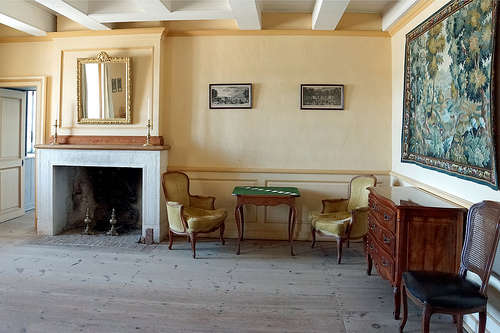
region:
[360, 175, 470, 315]
dark wood dresser beneath hanging rug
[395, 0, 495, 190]
decorative woven rug hanging on wall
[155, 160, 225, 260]
yellow chair next to fireplace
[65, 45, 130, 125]
mirror in gold frame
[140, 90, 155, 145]
candlestick with white candle on mantle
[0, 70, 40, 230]
open beige door into hallway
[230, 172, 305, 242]
small wood table between two chairs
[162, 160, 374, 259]
There are two antique chairs in green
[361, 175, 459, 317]
there is a dresser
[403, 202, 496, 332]
There's a blue wooden chair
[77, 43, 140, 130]
there is a mirror above the fireplace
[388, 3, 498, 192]
there is a large painting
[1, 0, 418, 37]
there are white rafters on the ceiling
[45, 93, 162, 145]
there are candles on the fireplace mantle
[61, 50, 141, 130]
mirror with gold frame on the wall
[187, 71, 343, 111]
a set of two painting on the wall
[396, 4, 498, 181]
large picture hanging covering the wall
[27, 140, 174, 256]
white fireplace next to the door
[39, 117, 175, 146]
two candle sticks on the fireplace mantel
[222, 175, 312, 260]
a table with a green covering on top of it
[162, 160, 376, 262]
two matching chairs on either side of table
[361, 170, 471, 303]
wooden chest with three drawers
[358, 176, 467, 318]
a wooden chest with drawers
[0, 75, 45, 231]
open door next to the fireplace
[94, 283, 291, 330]
The flooring is gray in color.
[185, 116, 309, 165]
The walls are biege in color.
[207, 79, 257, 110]
The picture frame is dark in color.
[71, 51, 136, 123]
The mirror is hanging from the wall.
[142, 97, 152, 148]
The candle is on the mantle.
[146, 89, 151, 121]
The candle is white in color.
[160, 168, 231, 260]
The seat is yellow.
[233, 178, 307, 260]
The table is made of wood.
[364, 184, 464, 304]
The dresser is made of wood.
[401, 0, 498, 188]
The rug is hanging from the wall.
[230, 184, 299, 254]
The table with the green top.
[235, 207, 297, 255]
The legs of the green top table.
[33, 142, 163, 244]
The fireplace in the room.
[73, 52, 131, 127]
The mirror above the fireplace.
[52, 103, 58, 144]
The candelabra on the left side of the mantle.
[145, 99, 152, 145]
The candelabra on the right side of the mantle.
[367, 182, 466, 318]
The dresser against the wall.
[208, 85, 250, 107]
The frame on the left.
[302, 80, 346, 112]
The frame on the right.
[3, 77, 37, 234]
The doorway in the room.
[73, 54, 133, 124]
Mirror over the fireplace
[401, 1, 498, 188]
Large tapestry on the wall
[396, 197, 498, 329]
Chair to the right of the dresser